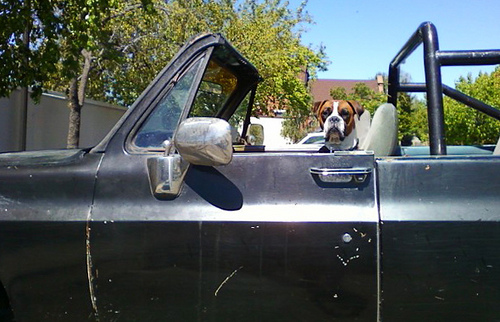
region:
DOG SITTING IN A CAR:
[67, 21, 409, 198]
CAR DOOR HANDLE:
[302, 148, 385, 196]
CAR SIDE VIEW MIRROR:
[139, 108, 251, 194]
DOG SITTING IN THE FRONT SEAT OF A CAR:
[294, 83, 412, 155]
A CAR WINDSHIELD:
[106, 21, 270, 141]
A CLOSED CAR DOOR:
[80, 143, 400, 313]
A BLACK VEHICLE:
[11, 17, 498, 313]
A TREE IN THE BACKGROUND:
[49, 0, 209, 147]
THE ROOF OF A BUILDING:
[296, 71, 394, 99]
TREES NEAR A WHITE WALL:
[6, 10, 103, 147]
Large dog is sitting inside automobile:
[288, 86, 384, 192]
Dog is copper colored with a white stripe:
[294, 78, 388, 176]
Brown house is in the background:
[253, 53, 407, 123]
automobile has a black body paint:
[0, 37, 498, 317]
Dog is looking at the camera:
[295, 81, 365, 173]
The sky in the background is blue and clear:
[270, 0, 490, 80]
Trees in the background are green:
[0, 0, 295, 110]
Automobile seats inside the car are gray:
[350, 90, 406, 170]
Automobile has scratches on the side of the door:
[160, 220, 356, 320]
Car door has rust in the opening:
[77, 203, 108, 318]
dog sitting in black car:
[163, 24, 478, 295]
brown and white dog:
[288, 86, 392, 191]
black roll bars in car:
[383, 18, 490, 176]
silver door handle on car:
[306, 151, 377, 201]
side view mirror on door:
[136, 90, 238, 206]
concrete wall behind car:
[8, 71, 137, 160]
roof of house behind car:
[271, 56, 403, 125]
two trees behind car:
[13, 17, 100, 139]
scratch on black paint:
[193, 248, 259, 304]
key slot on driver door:
[332, 226, 368, 255]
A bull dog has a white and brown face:
[301, 95, 378, 144]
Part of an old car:
[13, 106, 274, 288]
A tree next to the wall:
[14, 6, 116, 148]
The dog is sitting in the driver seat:
[143, 31, 399, 153]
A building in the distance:
[303, 72, 383, 99]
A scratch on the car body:
[181, 247, 256, 304]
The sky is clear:
[326, 5, 383, 62]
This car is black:
[390, 228, 469, 300]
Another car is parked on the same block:
[276, 132, 323, 146]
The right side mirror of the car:
[166, 100, 238, 163]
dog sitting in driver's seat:
[171, 56, 408, 212]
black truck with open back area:
[26, 40, 466, 295]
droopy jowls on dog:
[295, 95, 361, 145]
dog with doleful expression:
[301, 67, 366, 147]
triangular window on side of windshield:
[107, 40, 232, 165]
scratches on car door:
[176, 220, 367, 305]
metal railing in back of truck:
[377, 15, 482, 151]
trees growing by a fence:
[15, 1, 345, 126]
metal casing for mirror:
[140, 107, 252, 202]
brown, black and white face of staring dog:
[296, 77, 374, 157]